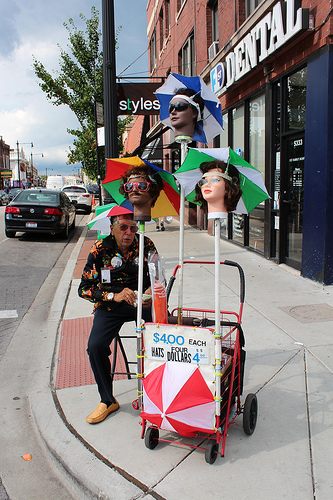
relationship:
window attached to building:
[285, 71, 306, 256] [131, 6, 332, 289]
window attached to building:
[276, 143, 309, 276] [144, 0, 332, 280]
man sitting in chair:
[76, 212, 168, 425] [76, 285, 178, 406]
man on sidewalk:
[77, 169, 167, 469] [45, 165, 331, 487]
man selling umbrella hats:
[77, 169, 167, 469] [36, 55, 280, 250]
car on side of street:
[1, 176, 85, 256] [0, 104, 118, 496]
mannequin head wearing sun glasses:
[156, 74, 215, 159] [147, 96, 202, 123]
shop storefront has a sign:
[174, 17, 326, 297] [218, 0, 310, 105]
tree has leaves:
[55, 16, 118, 208] [38, 7, 119, 191]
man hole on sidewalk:
[276, 281, 331, 335] [67, 188, 331, 494]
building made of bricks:
[134, 4, 331, 245] [127, 0, 326, 131]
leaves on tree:
[44, 10, 134, 197] [38, 14, 114, 208]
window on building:
[265, 46, 317, 297] [116, 0, 331, 286]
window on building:
[269, 79, 282, 259] [86, 0, 326, 293]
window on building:
[187, 109, 259, 167] [96, 3, 331, 277]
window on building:
[147, 26, 161, 71] [144, 0, 332, 280]